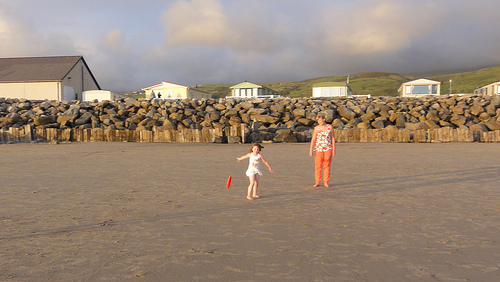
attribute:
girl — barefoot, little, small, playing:
[235, 142, 274, 203]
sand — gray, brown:
[1, 140, 498, 280]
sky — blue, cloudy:
[1, 0, 499, 90]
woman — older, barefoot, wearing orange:
[308, 115, 337, 189]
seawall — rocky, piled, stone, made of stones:
[2, 94, 500, 145]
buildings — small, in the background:
[226, 80, 283, 98]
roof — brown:
[1, 55, 105, 89]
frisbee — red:
[226, 176, 232, 189]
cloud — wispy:
[162, 3, 296, 53]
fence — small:
[1, 125, 500, 143]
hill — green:
[120, 64, 499, 96]